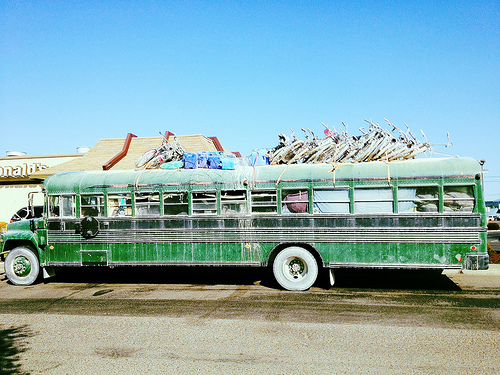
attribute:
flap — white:
[318, 265, 358, 294]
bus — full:
[35, 143, 496, 298]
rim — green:
[12, 254, 31, 279]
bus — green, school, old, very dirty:
[0, 155, 490, 292]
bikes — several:
[266, 124, 456, 164]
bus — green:
[16, 143, 498, 310]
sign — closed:
[79, 217, 99, 237]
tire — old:
[269, 242, 328, 302]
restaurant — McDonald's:
[1, 115, 191, 219]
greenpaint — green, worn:
[3, 167, 483, 267]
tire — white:
[269, 243, 322, 295]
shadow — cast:
[4, 324, 31, 374]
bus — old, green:
[9, 172, 481, 282]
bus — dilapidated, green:
[9, 159, 494, 311]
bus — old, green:
[38, 104, 491, 345]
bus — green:
[10, 149, 494, 326]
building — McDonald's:
[47, 122, 242, 182]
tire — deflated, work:
[261, 234, 326, 294]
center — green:
[284, 254, 305, 277]